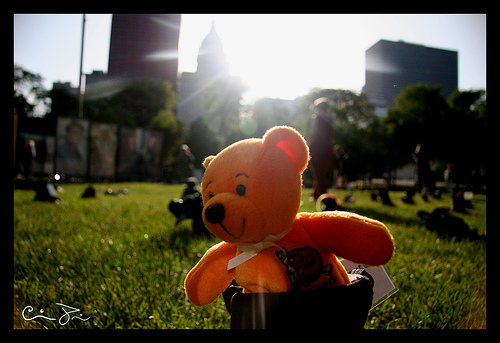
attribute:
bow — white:
[224, 234, 288, 270]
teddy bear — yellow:
[175, 117, 397, 303]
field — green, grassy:
[1, 182, 492, 338]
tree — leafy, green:
[367, 71, 462, 204]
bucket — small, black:
[219, 266, 382, 341]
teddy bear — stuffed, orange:
[177, 131, 409, 324]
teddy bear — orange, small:
[163, 106, 408, 338]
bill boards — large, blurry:
[38, 95, 180, 223]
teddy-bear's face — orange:
[165, 99, 312, 231]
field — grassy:
[39, 164, 464, 339]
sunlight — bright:
[141, 15, 438, 186]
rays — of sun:
[185, 0, 415, 145]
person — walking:
[301, 84, 344, 229]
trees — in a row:
[305, 61, 497, 253]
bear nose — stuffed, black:
[185, 182, 238, 244]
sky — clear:
[152, 15, 421, 117]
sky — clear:
[189, 0, 398, 154]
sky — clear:
[171, 18, 391, 188]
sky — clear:
[0, 34, 174, 134]